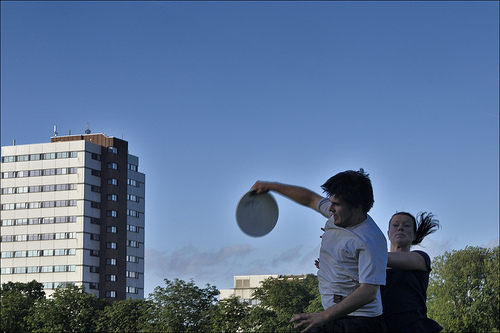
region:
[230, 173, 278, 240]
man holding a frisbee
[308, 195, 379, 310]
man wearing a white tee shirt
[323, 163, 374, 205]
man with black hair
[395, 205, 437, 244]
woman with black hair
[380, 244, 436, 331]
woman wearing a black shirt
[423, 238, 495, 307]
leaves on a tree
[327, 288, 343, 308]
logo on a tee shirt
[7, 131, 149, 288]
high rise building in the city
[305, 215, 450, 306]
woman grabbing a man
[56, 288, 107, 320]
leaves in front of a building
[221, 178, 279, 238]
Frisbee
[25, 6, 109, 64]
whiate clouds in blue sky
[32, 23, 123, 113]
whiate clouds in blue sky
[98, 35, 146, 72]
whiate clouds in blue sky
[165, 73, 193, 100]
whiate clouds in blue sky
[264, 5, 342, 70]
whiate clouds in blue sky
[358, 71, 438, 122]
whiate clouds in blue sky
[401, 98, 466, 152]
whiate clouds in blue sky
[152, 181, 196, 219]
whiate clouds in blue sky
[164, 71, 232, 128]
whiate clouds in blue sky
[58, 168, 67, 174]
window on the building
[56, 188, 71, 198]
window on the building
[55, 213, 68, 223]
window on the building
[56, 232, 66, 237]
window on the building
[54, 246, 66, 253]
window on the building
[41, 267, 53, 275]
window on the building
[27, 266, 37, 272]
window on the building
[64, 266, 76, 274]
window on the building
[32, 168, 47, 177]
window on the building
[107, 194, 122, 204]
window on the building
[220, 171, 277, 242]
white Frisbee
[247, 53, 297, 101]
white clouds in blue sky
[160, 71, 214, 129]
white clouds in blue sky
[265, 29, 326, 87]
white clouds in blue sky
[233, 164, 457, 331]
A couple playing frisbee in the park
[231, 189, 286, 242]
A circular white frisbee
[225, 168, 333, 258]
The man is holding a white frisbee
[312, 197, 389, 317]
A white shirt on the man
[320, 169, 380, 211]
The man has short black hair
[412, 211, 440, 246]
The woman has a long black ponytail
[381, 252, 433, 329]
A black tee shirt on the woman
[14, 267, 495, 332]
A row of green trees behind the couple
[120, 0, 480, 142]
An open blue sky above the couple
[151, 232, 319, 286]
Wispy grey clouds in the sky